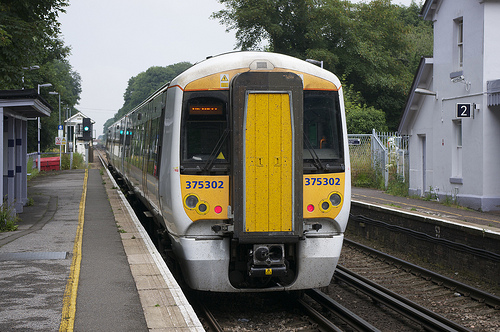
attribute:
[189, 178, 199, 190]
number — painted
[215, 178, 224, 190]
number — painted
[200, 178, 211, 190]
number — painted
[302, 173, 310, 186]
number — painted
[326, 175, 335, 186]
number — painted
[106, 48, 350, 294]
train — bringing, running late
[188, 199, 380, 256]
lamps — head light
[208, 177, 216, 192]
number — painted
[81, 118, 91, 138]
light — green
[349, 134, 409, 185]
fence — white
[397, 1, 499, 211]
building — gray, white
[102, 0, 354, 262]
train's — yellow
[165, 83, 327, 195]
windows — dark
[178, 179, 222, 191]
number — painted